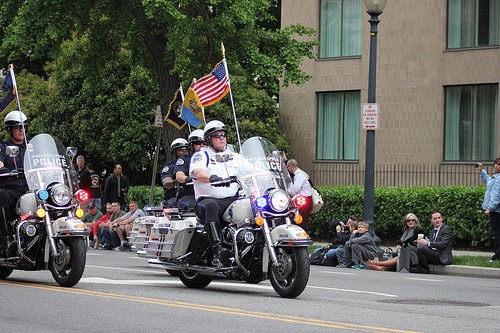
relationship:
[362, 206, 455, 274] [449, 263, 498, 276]
couple sitting on curb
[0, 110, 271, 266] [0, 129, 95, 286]
police rides bike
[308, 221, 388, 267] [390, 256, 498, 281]
kids sit on curb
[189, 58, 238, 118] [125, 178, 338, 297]
usa flag on motorcycle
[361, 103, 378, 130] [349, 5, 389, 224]
sign on pole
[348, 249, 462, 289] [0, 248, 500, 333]
line in road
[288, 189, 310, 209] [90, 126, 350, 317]
light on motorcycle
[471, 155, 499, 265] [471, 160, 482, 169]
person holding camera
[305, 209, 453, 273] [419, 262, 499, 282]
people on curb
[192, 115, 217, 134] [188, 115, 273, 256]
helmet on police officer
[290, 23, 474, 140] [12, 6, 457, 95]
building in background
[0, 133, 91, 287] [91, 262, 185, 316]
bike on road